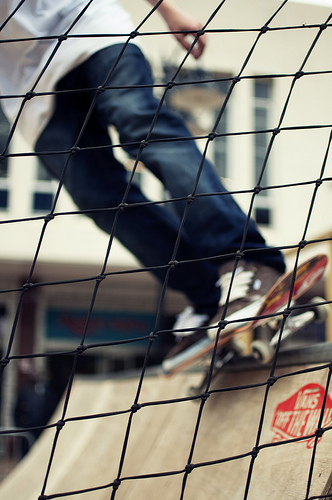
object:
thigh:
[110, 46, 157, 152]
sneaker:
[206, 260, 283, 341]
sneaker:
[161, 303, 215, 371]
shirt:
[0, 0, 140, 148]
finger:
[180, 41, 200, 60]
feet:
[161, 294, 217, 372]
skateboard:
[160, 248, 328, 383]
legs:
[36, 112, 208, 304]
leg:
[89, 42, 265, 269]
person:
[0, 4, 284, 363]